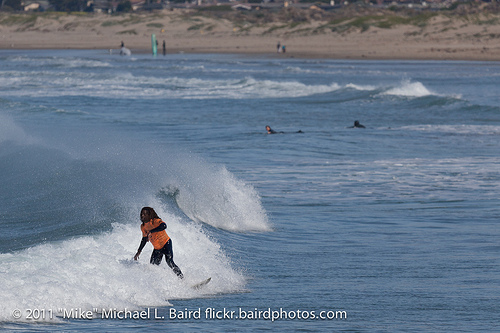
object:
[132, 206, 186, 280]
man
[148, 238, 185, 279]
pants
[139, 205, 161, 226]
dreadlocks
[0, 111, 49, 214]
water splashes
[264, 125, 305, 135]
people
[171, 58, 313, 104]
waves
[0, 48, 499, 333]
ocean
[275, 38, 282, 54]
people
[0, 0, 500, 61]
beach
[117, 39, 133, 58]
rock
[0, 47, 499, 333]
water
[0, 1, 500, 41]
grass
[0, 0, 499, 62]
sandy hill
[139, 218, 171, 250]
orange shirt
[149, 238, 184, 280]
black pants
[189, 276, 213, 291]
surf board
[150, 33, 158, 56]
green board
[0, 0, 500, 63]
sandy beach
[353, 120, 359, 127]
head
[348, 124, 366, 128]
wetsuit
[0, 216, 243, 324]
waves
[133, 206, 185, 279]
lady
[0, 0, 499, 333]
photo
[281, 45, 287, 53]
people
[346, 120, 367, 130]
people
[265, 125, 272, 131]
head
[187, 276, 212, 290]
tip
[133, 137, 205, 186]
sprinkles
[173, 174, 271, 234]
wave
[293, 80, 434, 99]
wave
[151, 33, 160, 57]
pole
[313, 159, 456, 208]
ripples